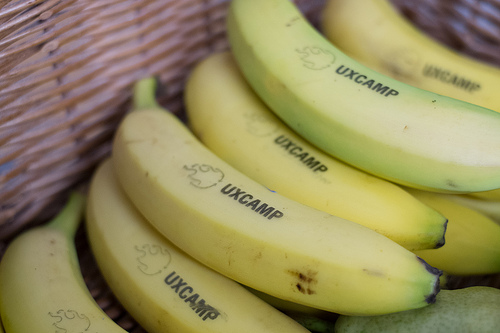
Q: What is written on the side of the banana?
A: UXCAMP.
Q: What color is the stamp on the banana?
A: Black.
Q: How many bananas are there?
A: 7.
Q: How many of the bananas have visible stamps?
A: 6.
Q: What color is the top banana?
A: Green and yellow.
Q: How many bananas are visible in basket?
A: Seven.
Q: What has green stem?
A: Yellow banana.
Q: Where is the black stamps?
A: On the yellow bananas.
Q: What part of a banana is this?
A: Bottom of a banana peel.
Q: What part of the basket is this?
A: Brown woven side.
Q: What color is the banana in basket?
A: Yellow.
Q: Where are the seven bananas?
A: In a basket.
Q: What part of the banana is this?
A: Top.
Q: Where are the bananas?
A: In a basket.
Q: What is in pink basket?
A: Black lines.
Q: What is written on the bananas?
A: Uxcamp.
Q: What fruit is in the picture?
A: Bananas.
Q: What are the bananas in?
A: A basket.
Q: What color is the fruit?
A: Yellow.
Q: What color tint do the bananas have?
A: Greenish.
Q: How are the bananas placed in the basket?
A: Individually.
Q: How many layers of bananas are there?
A: Three.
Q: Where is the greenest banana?
A: On top.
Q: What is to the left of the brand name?
A: A logo.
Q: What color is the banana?
A: Yellow.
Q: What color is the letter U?
A: Black.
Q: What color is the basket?
A: Brown.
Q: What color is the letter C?
A: Black.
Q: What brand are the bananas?
A: Uxcamp.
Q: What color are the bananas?
A: Yellow.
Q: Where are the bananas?
A: In a basket.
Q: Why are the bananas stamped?
A: For the brand.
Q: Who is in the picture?
A: Nobody.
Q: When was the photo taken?
A: Daytime.